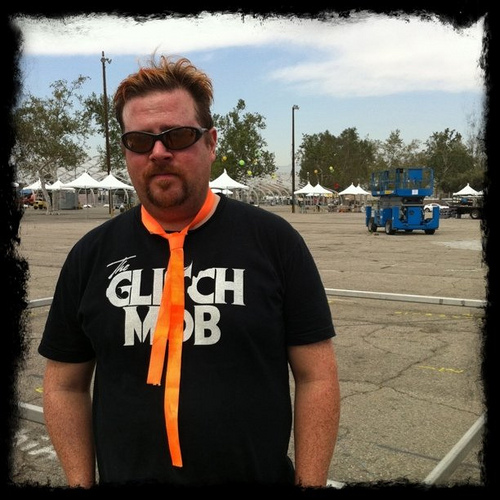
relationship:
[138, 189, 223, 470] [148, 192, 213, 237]
ribbon around neck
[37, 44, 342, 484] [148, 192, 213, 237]
man has neck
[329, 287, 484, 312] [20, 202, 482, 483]
line on pavement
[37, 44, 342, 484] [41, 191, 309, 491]
man wearing t shirt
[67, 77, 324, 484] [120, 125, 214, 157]
man wearing sunglasses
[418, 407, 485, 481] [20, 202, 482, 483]
white line on pavement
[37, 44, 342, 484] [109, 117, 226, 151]
man has sunglasses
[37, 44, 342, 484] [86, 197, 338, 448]
man wearing a shirt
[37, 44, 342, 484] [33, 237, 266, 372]
man with lettering